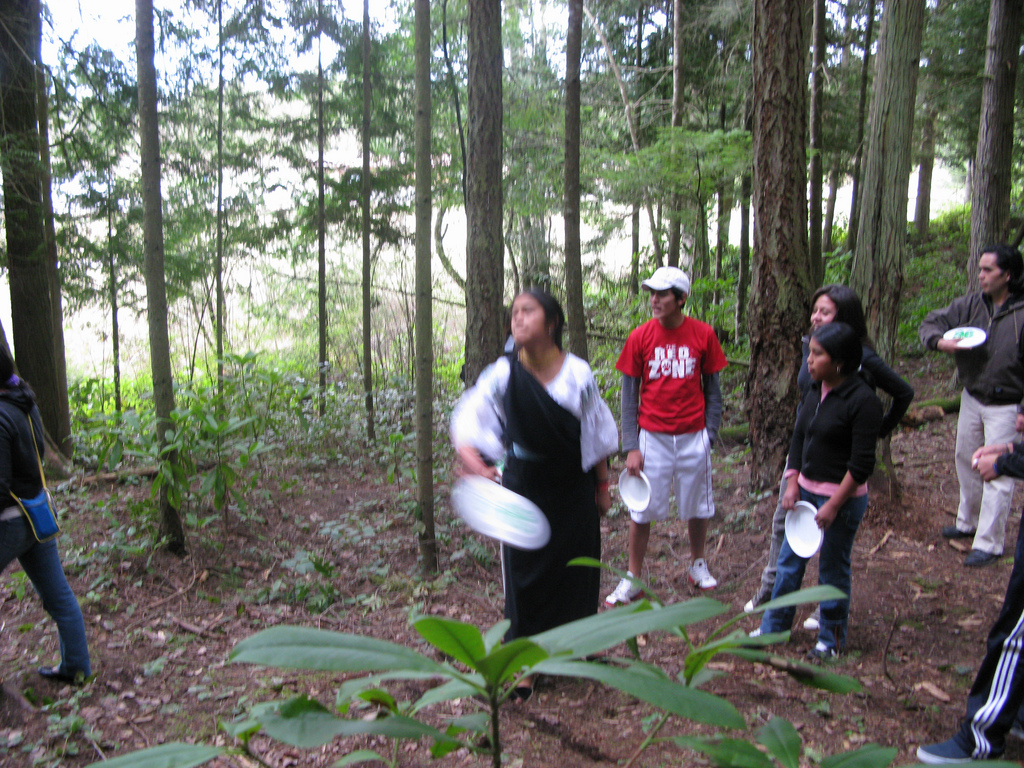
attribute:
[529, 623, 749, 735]
leaves — green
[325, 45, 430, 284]
leaves — green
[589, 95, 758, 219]
leaves — green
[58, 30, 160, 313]
leaves — green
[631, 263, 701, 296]
cap — white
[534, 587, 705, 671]
plant — large, green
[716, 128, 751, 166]
leaf — green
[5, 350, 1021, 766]
branches — broken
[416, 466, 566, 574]
frisbee — green, white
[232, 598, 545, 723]
leaves — green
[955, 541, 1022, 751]
leg — white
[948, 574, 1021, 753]
pants — black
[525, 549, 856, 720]
leaves — green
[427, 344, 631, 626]
dress — black, white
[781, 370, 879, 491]
sweater — black